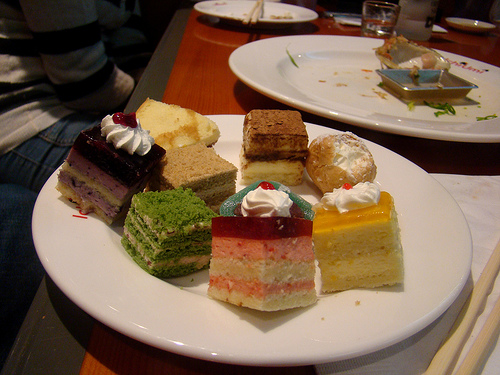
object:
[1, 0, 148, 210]
person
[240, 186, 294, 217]
cream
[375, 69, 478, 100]
cup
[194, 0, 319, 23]
empty plate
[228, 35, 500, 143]
empty plate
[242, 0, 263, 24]
chopsticks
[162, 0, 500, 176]
ground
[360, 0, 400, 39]
glass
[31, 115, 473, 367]
plate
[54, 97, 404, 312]
cakes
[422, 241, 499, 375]
chopstick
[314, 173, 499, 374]
napkin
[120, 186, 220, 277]
dessert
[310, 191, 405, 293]
dessert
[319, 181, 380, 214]
whip cream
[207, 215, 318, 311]
dessert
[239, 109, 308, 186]
dessert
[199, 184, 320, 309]
petit four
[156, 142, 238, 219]
petit four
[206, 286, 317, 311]
layer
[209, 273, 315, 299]
layer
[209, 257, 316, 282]
layer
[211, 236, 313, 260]
layer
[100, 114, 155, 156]
cream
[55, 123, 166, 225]
dessert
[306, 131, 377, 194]
dessert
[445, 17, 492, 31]
saucer